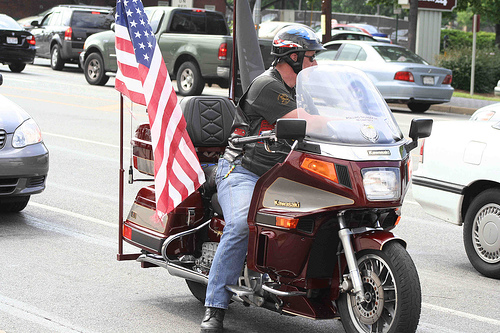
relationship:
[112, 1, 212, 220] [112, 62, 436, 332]
flag on motorcycle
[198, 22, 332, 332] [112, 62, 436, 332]
man riding motorcycle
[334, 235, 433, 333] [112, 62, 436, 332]
wheel on motorcycle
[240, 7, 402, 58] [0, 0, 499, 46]
vehicles in background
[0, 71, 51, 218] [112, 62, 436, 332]
car behind motorcycle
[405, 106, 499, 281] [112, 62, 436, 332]
car adjacent to motorcycle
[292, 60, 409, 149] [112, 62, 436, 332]
windshield on motorcycle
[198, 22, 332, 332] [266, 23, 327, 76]
man wearing helmet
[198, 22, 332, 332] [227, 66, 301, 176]
man wearing jacket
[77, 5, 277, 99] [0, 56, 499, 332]
pick-up truck on road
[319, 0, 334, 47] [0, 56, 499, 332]
post on side of road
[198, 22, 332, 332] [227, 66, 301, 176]
man wearing vest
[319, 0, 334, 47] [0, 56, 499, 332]
post near road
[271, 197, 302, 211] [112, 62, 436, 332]
lettering on motorcycle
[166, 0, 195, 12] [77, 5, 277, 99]
sign behind pick-up truck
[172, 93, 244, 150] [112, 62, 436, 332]
seat back on motorcycle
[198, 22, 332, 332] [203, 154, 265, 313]
man wearing jeans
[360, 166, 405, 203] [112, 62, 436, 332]
headlight on motorcycle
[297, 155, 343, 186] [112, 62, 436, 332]
turn signal on motorcycle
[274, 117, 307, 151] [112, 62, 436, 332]
mirrors on motorcycle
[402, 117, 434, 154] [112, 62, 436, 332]
left mirror on motorcycle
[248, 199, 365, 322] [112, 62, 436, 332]
left front fender on motorcycle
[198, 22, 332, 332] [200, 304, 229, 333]
man wearing shoe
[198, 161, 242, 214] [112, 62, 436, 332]
seat on motorcycle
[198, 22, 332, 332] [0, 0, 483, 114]
man looking at traffic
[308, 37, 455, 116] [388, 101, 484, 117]
car parked on curb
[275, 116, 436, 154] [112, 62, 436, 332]
mirrors on motorcycle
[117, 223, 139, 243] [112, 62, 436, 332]
reflector on back of motorcycle